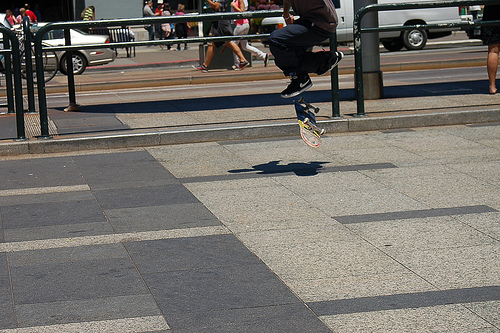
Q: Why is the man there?
A: To ride his skateboard.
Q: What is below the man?
A: The sidewalk.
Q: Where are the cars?
A: The street.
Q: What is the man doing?
A: Doing a skateboard trick.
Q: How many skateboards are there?
A: One.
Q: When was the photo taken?
A: During the day.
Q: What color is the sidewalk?
A: Grey.